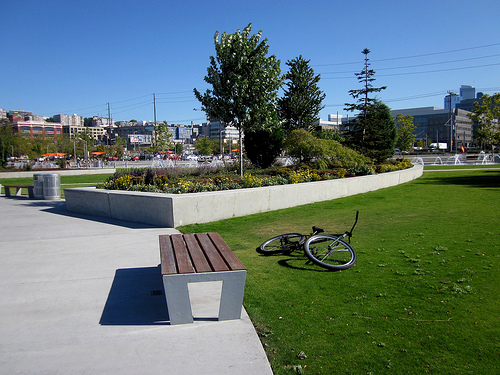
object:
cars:
[134, 156, 139, 161]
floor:
[0, 164, 500, 375]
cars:
[173, 152, 185, 160]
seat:
[155, 230, 245, 281]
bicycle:
[255, 207, 362, 274]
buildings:
[2, 115, 64, 158]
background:
[0, 1, 500, 373]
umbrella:
[40, 150, 65, 160]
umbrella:
[87, 149, 105, 158]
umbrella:
[158, 150, 170, 153]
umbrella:
[230, 146, 245, 153]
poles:
[148, 88, 161, 167]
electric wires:
[157, 40, 500, 97]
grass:
[175, 168, 500, 374]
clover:
[396, 247, 405, 256]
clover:
[376, 291, 385, 298]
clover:
[456, 278, 466, 284]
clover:
[433, 243, 443, 252]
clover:
[375, 260, 390, 270]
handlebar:
[346, 229, 358, 241]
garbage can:
[40, 172, 62, 201]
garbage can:
[31, 171, 43, 202]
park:
[1, 25, 500, 373]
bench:
[155, 230, 253, 323]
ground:
[0, 171, 500, 374]